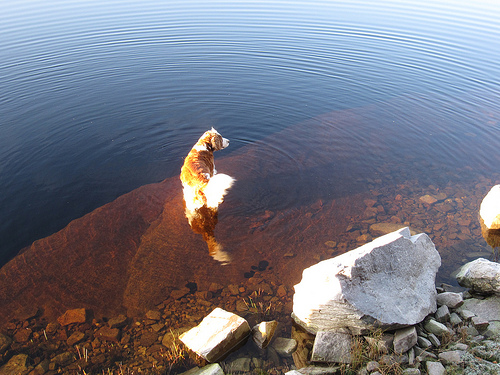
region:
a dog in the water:
[177, 124, 238, 271]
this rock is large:
[287, 218, 441, 335]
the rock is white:
[286, 215, 441, 342]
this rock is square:
[175, 303, 252, 365]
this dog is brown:
[163, 122, 243, 270]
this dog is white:
[176, 122, 238, 268]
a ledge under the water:
[2, 80, 499, 352]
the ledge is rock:
[2, 87, 496, 345]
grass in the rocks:
[342, 327, 478, 374]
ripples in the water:
[24, 3, 499, 280]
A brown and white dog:
[178, 126, 235, 263]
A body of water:
[1, 0, 498, 373]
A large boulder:
[291, 223, 441, 333]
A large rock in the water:
[176, 306, 252, 362]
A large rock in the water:
[477, 182, 498, 232]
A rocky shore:
[180, 183, 497, 374]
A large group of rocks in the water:
[0, 123, 492, 374]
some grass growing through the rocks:
[343, 329, 498, 374]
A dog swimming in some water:
[177, 123, 245, 266]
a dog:
[174, 120, 233, 262]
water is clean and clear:
[1, 11, 494, 368]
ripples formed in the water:
[12, 2, 494, 126]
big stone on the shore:
[148, 190, 498, 367]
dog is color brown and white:
[140, 101, 274, 276]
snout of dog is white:
[221, 131, 236, 151]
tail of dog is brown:
[193, 227, 236, 272]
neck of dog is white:
[186, 130, 211, 157]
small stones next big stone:
[383, 276, 493, 373]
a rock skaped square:
[170, 303, 256, 365]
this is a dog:
[183, 123, 238, 224]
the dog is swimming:
[173, 123, 244, 236]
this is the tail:
[198, 173, 235, 207]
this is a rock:
[310, 228, 445, 328]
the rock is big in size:
[298, 230, 438, 327]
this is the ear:
[201, 140, 210, 151]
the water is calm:
[296, 24, 444, 154]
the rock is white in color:
[341, 246, 408, 307]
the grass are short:
[346, 339, 376, 371]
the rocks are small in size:
[408, 325, 467, 371]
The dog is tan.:
[167, 112, 238, 214]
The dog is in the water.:
[173, 115, 237, 237]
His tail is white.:
[200, 170, 237, 211]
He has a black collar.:
[198, 130, 220, 152]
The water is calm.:
[17, 9, 489, 134]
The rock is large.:
[283, 221, 449, 341]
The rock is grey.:
[293, 221, 439, 335]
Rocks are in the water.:
[37, 285, 297, 329]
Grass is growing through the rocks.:
[346, 331, 396, 373]